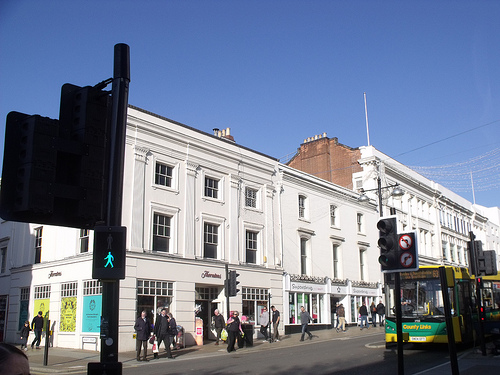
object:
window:
[205, 176, 218, 199]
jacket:
[299, 311, 313, 324]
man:
[269, 306, 280, 343]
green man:
[104, 252, 114, 269]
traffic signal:
[92, 226, 125, 279]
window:
[155, 161, 172, 187]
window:
[246, 230, 256, 265]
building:
[469, 202, 499, 273]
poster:
[59, 297, 77, 333]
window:
[80, 230, 89, 254]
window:
[153, 212, 172, 252]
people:
[214, 309, 225, 345]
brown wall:
[285, 138, 373, 198]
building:
[283, 132, 478, 336]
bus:
[381, 265, 499, 345]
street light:
[357, 185, 405, 203]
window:
[245, 187, 256, 209]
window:
[331, 206, 335, 226]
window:
[360, 250, 365, 280]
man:
[31, 311, 44, 350]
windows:
[333, 244, 339, 277]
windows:
[138, 280, 172, 296]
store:
[5, 250, 286, 352]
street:
[0, 315, 500, 374]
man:
[107, 234, 114, 249]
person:
[165, 313, 178, 351]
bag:
[149, 336, 159, 353]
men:
[18, 320, 32, 349]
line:
[381, 117, 500, 162]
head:
[141, 308, 149, 316]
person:
[19, 321, 32, 350]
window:
[35, 226, 42, 264]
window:
[204, 222, 218, 260]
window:
[333, 245, 337, 279]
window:
[299, 195, 304, 217]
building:
[0, 99, 281, 351]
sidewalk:
[0, 313, 500, 375]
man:
[153, 309, 174, 359]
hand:
[154, 334, 157, 336]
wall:
[4, 252, 104, 352]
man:
[134, 310, 151, 362]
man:
[227, 311, 245, 354]